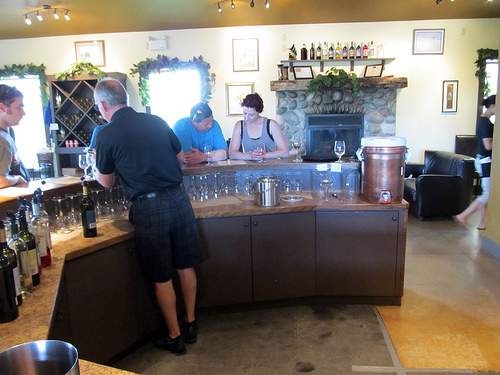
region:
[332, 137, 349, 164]
A clear wine glass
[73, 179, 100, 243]
A bottle of alcohol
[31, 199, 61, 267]
A bottle of alcohol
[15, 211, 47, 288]
A bottle of alcohol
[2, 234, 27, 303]
A bottle of alcohol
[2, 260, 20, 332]
A bottle of alcohol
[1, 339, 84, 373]
A silver metal bowl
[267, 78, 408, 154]
A stone fireplace in the background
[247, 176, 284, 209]
A silver ice bucket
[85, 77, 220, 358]
A male bartender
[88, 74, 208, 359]
Bartender wearing black shirt, black plaid shorts and black shoes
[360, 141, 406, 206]
Two and a half gallon thermal dispenser covered jug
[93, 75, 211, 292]
Man wearing black plaid pants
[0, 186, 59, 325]
Assorted bottles of mixing liqueur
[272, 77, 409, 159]
Stone faced fire place with black doors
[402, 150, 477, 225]
Upholstered leather like chair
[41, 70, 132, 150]
Diamond cubby shelved wine bottle storage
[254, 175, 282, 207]
Stainless steel ice bucket with top and handle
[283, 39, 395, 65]
Shelf with assorted bottles of spirits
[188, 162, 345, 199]
Various glass glasses stored under bar top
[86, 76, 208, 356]
an older man in shorts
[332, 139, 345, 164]
a clear wine glass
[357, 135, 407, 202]
a beverage dispenser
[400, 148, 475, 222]
a black leather couch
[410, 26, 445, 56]
a framed picture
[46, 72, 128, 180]
a wooden wine rack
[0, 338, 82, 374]
a silver metal bowl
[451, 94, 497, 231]
a woman walking through a doorway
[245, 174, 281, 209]
a shiny silver bucket with lid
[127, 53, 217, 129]
an ivy framed window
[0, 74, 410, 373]
bartender in black shorts and black shirt behind bar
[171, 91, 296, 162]
man and woman sitting at bar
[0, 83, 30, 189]
man standing at bar getting drink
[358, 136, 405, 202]
insulated beverage dispenser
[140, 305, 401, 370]
non-slip mat on floor behind bar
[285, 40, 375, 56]
collection of bottles on shelf above fireplace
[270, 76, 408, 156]
fireplace made from natural stone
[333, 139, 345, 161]
glass for wine or beer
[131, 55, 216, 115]
Christmas wreath around window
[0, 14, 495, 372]
patrons at open bar in rustic great room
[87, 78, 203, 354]
a bartender behind a bar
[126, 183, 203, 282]
man wearing plaid shorts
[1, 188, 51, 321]
a row of bottle on a bar counter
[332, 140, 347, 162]
an empty glass of wine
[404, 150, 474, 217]
a black leather couch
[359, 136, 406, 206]
a barrel like cooler with a white lid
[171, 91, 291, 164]
a man and a woman standing at a bar counter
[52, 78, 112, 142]
bottles on display on a rack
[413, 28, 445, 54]
a framed diploma on a wall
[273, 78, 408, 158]
a stone fireplace